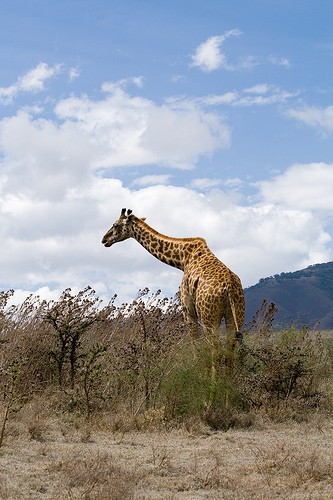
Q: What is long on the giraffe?
A: Neck.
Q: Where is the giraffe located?
A: In the wild.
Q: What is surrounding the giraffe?
A: Bushes.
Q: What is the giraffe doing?
A: Standing around.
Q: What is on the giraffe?
A: Spots.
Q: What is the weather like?
A: Partly cloudy.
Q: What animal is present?
A: Giraffe.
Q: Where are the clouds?
A: In the sky.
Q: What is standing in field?
A: Tall giraffe.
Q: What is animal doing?
A: Traveling thru field.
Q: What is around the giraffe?
A: Weeds.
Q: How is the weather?
A: Blue sky and cloudy.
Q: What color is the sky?
A: Blue.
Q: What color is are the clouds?
A: White.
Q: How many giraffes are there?
A: One.